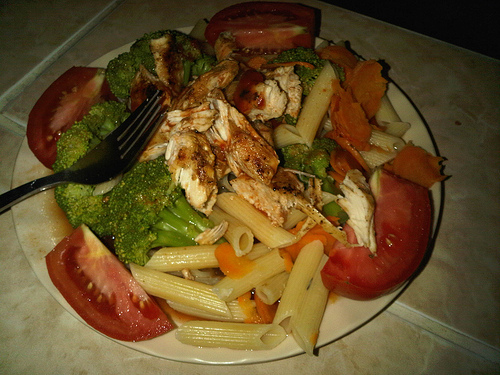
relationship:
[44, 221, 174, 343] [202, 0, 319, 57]
slice of tomato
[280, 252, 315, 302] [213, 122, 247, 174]
penne with chicken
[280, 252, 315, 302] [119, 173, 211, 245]
penne with broccoli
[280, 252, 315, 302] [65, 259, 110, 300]
penne with tomatos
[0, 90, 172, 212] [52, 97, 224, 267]
fork resting on broccoli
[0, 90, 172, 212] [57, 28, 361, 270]
fork resting on broccoli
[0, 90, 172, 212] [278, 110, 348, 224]
fork resting on broccoli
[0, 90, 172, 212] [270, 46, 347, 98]
fork resting on broccoli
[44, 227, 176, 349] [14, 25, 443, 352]
tomato on plate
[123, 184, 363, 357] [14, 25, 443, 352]
pasta on plate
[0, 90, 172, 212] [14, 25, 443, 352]
fork propped on plate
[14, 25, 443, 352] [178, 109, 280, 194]
plate with chicken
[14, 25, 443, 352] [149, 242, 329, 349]
plate with pasta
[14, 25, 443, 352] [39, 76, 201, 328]
plate with veggies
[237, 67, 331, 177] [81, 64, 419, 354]
tuna on penne pasta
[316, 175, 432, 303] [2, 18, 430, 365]
tomato cut up on plate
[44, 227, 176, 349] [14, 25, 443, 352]
tomato cut up on plate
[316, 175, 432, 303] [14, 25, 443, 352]
tomato on plate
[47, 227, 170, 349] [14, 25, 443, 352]
tomato on plate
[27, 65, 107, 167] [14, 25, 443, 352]
tomato on plate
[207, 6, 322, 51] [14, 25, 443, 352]
tomato on plate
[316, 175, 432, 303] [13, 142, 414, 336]
tomato on plate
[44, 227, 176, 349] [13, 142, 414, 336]
tomato on plate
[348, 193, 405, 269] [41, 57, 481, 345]
tomato on plate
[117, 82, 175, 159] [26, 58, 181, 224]
prong on fork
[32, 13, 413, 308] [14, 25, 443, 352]
tomato on a plate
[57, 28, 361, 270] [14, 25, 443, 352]
broccoli on a plate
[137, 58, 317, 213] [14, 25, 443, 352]
chicken on a plate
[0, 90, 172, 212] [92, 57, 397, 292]
fork in a meal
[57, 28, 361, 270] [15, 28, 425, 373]
broccoli in a meal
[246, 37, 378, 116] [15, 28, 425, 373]
broccoli in a meal